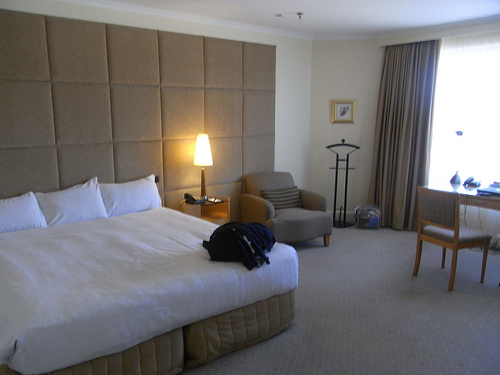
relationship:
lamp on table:
[186, 129, 215, 199] [177, 186, 235, 223]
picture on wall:
[328, 96, 358, 127] [308, 16, 499, 225]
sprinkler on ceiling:
[289, 6, 311, 25] [148, 3, 497, 42]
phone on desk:
[460, 174, 485, 193] [426, 171, 500, 216]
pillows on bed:
[5, 175, 162, 232] [3, 169, 301, 374]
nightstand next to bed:
[177, 186, 235, 223] [3, 169, 301, 374]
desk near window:
[426, 171, 500, 216] [422, 31, 499, 194]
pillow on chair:
[259, 179, 307, 210] [238, 166, 339, 251]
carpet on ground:
[170, 210, 495, 374] [173, 189, 497, 371]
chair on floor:
[412, 180, 493, 292] [170, 210, 495, 374]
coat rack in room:
[323, 136, 356, 230] [3, 1, 498, 370]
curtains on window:
[368, 36, 439, 238] [422, 31, 499, 194]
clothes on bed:
[207, 214, 279, 276] [3, 169, 301, 374]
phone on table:
[460, 174, 485, 193] [426, 171, 500, 216]